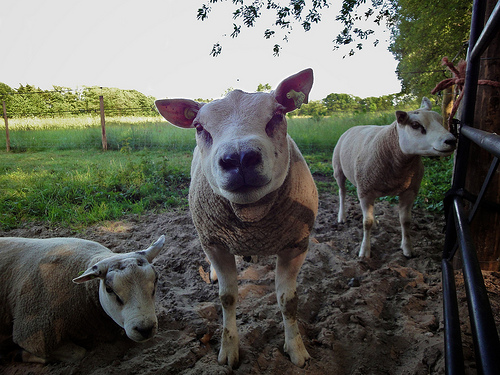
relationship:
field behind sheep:
[48, 92, 414, 199] [167, 74, 369, 373]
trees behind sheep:
[0, 0, 500, 129] [17, 71, 446, 225]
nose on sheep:
[133, 319, 155, 339] [1, 232, 171, 362]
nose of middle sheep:
[216, 147, 265, 174] [149, 59, 336, 373]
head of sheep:
[83, 237, 182, 342] [11, 96, 191, 374]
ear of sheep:
[62, 254, 107, 286] [53, 222, 246, 351]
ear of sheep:
[137, 67, 208, 137] [144, 82, 355, 365]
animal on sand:
[0, 235, 165, 375] [3, 182, 498, 372]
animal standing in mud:
[330, 102, 452, 257] [9, 190, 479, 372]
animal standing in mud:
[156, 65, 316, 361] [9, 190, 479, 372]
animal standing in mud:
[6, 237, 168, 371] [9, 190, 479, 372]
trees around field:
[0, 2, 470, 110] [0, 113, 432, 375]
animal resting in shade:
[0, 235, 165, 375] [0, 164, 433, 371]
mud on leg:
[274, 289, 306, 322] [252, 261, 336, 362]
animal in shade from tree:
[0, 235, 165, 375] [389, 0, 483, 96]